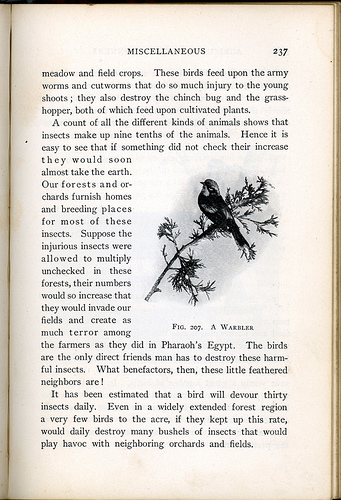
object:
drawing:
[141, 152, 288, 318]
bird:
[198, 179, 258, 257]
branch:
[144, 176, 278, 306]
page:
[7, 3, 335, 500]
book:
[0, 2, 341, 500]